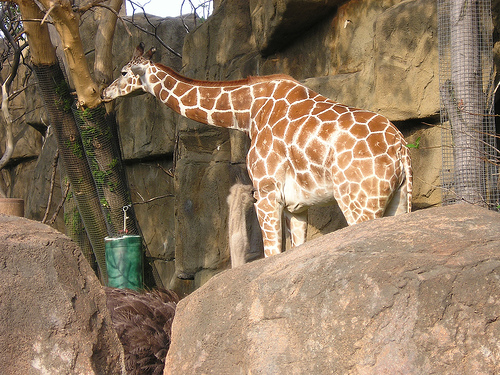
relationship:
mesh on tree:
[31, 57, 116, 287] [16, 0, 116, 288]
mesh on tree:
[14, 56, 163, 294] [41, 2, 157, 287]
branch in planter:
[1, 32, 21, 174] [1, 192, 31, 219]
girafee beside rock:
[122, 65, 414, 220] [313, 17, 467, 117]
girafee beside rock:
[122, 65, 414, 220] [191, 21, 260, 87]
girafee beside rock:
[122, 65, 414, 220] [170, 129, 257, 264]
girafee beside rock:
[122, 65, 414, 220] [33, 32, 100, 219]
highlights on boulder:
[247, 290, 311, 365] [144, 194, 494, 367]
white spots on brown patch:
[309, 145, 320, 157] [285, 146, 309, 173]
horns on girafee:
[131, 38, 162, 60] [99, 47, 415, 258]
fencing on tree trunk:
[422, 3, 486, 220] [447, 3, 488, 198]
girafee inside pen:
[99, 47, 415, 258] [0, 122, 202, 314]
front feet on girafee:
[244, 173, 418, 286] [99, 47, 415, 258]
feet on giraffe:
[337, 199, 404, 246] [92, 30, 435, 270]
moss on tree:
[72, 103, 129, 203] [41, 2, 157, 287]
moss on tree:
[72, 103, 129, 203] [16, 0, 116, 288]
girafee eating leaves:
[99, 47, 415, 258] [65, 66, 112, 133]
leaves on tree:
[65, 66, 112, 133] [12, 1, 169, 292]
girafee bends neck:
[99, 47, 415, 258] [143, 60, 285, 131]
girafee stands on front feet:
[99, 47, 415, 258] [251, 181, 296, 259]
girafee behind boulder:
[99, 47, 415, 258] [165, 203, 499, 374]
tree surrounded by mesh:
[429, 1, 496, 210] [436, 102, 490, 193]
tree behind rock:
[12, 0, 147, 286] [0, 214, 123, 374]